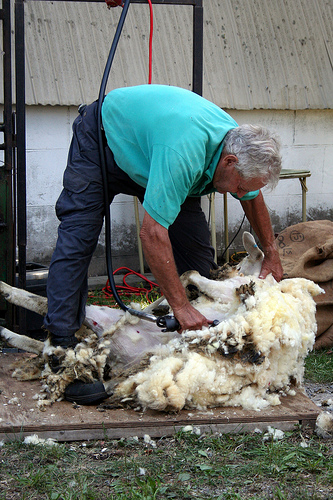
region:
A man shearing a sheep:
[42, 75, 315, 400]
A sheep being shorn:
[1, 204, 331, 418]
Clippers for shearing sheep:
[97, 261, 233, 342]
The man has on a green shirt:
[32, 66, 280, 362]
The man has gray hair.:
[193, 107, 303, 220]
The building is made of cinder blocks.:
[9, 87, 318, 243]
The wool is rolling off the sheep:
[115, 299, 321, 415]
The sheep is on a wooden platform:
[2, 277, 307, 456]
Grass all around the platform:
[5, 397, 328, 486]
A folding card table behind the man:
[156, 121, 318, 263]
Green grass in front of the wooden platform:
[0, 433, 332, 499]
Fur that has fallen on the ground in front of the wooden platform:
[1, 411, 332, 473]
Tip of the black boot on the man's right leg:
[64, 378, 109, 404]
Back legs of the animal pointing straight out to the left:
[0, 279, 101, 357]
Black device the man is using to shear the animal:
[156, 315, 219, 332]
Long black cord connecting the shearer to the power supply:
[96, 1, 154, 323]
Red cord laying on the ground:
[86, 265, 163, 308]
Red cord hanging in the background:
[148, 0, 154, 83]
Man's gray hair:
[223, 123, 281, 194]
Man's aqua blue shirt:
[101, 84, 259, 228]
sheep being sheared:
[2, 240, 307, 415]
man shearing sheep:
[36, 70, 310, 410]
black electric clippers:
[98, 240, 224, 353]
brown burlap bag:
[266, 213, 332, 363]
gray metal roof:
[222, 5, 331, 119]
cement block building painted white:
[263, 110, 331, 223]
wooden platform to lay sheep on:
[3, 339, 332, 455]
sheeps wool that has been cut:
[135, 360, 223, 410]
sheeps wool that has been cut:
[265, 316, 314, 404]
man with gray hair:
[213, 112, 303, 224]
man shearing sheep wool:
[60, 88, 299, 413]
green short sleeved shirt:
[103, 84, 261, 229]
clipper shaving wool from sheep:
[151, 308, 224, 337]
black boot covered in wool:
[45, 338, 109, 406]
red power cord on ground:
[101, 262, 145, 301]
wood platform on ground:
[109, 400, 250, 445]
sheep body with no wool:
[115, 327, 152, 361]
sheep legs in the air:
[1, 287, 36, 349]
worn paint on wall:
[311, 184, 330, 219]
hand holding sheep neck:
[250, 252, 285, 284]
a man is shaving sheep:
[42, 84, 284, 408]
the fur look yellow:
[0, 268, 332, 479]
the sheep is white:
[0, 235, 283, 378]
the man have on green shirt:
[99, 82, 263, 231]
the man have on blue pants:
[44, 96, 221, 336]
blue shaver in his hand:
[84, 0, 223, 333]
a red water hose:
[84, 0, 160, 304]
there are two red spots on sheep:
[90, 317, 142, 339]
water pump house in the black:
[0, 0, 332, 282]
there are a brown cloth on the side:
[229, 213, 332, 360]